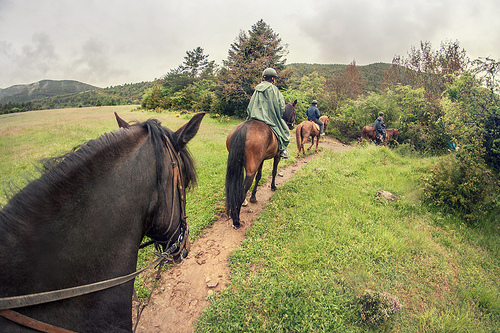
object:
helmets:
[260, 67, 278, 78]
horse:
[359, 125, 400, 146]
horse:
[294, 115, 332, 157]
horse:
[223, 99, 297, 227]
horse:
[1, 112, 207, 332]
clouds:
[75, 42, 125, 80]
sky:
[18, 2, 57, 16]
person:
[244, 65, 291, 158]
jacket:
[244, 81, 289, 150]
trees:
[146, 16, 292, 114]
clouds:
[307, 51, 334, 59]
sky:
[83, 18, 88, 36]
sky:
[5, 6, 51, 23]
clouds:
[369, 19, 387, 28]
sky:
[292, 3, 320, 14]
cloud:
[1, 30, 134, 96]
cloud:
[283, 2, 372, 34]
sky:
[469, 0, 500, 15]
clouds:
[297, 12, 326, 25]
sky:
[130, 12, 152, 20]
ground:
[297, 168, 353, 212]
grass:
[453, 228, 489, 244]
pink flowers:
[346, 287, 408, 331]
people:
[222, 67, 298, 228]